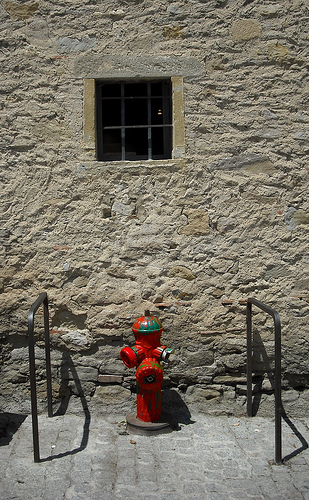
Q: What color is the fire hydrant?
A: Red.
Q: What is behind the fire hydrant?
A: A wall.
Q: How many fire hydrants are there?
A: One.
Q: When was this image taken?
A: Daytime.